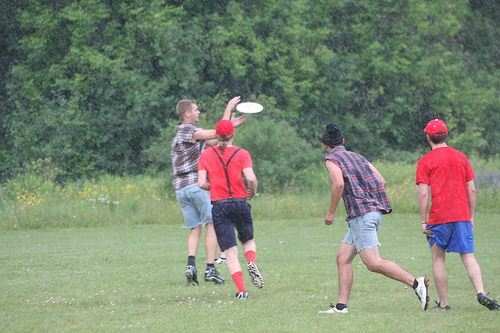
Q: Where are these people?
A: In a field.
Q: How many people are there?
A: Four.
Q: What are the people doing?
A: Playing frisby.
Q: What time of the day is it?
A: It is daytime.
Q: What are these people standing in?
A: Grass.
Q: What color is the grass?
A: Green.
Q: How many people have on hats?
A: Two.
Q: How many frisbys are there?
A: One.